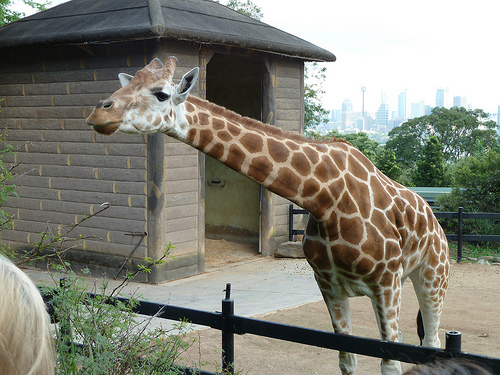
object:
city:
[305, 82, 499, 156]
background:
[292, 0, 498, 164]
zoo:
[2, 4, 498, 373]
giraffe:
[84, 44, 454, 373]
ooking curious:
[76, 53, 216, 153]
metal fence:
[57, 273, 498, 370]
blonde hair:
[0, 254, 63, 373]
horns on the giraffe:
[155, 52, 182, 81]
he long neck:
[181, 94, 318, 221]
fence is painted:
[87, 289, 498, 373]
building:
[1, 1, 334, 281]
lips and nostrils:
[97, 98, 117, 110]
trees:
[386, 107, 499, 250]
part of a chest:
[304, 229, 348, 261]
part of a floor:
[235, 273, 281, 307]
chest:
[300, 226, 373, 294]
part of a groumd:
[461, 262, 500, 327]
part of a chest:
[354, 234, 380, 269]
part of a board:
[130, 297, 204, 332]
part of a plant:
[430, 104, 484, 159]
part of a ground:
[251, 342, 311, 369]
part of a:
[307, 229, 358, 260]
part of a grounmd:
[242, 268, 303, 313]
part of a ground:
[238, 249, 313, 302]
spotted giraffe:
[92, 55, 463, 373]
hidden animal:
[36, 277, 76, 328]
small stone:
[467, 246, 488, 267]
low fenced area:
[439, 208, 498, 259]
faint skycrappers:
[335, 78, 488, 149]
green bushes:
[383, 103, 498, 187]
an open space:
[1, 8, 497, 373]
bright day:
[43, 9, 448, 300]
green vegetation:
[49, 273, 177, 371]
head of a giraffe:
[84, 60, 202, 140]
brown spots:
[313, 150, 339, 183]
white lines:
[229, 137, 260, 168]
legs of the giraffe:
[318, 290, 359, 374]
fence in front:
[54, 279, 399, 371]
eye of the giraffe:
[150, 90, 173, 105]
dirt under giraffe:
[295, 310, 479, 374]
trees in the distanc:
[389, 128, 489, 201]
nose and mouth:
[82, 97, 119, 137]